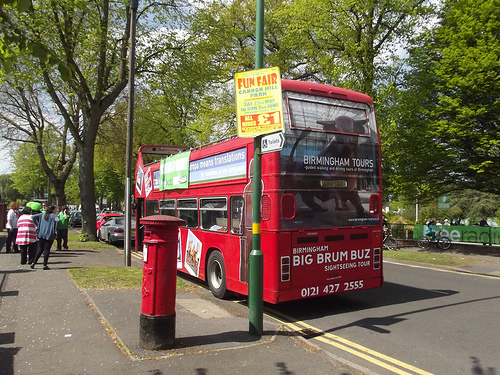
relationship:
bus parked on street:
[134, 79, 385, 304] [129, 240, 499, 375]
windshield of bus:
[282, 190, 381, 227] [134, 79, 385, 304]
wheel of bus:
[201, 250, 230, 304] [134, 79, 385, 304]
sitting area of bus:
[135, 129, 265, 168] [134, 79, 385, 304]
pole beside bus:
[247, 0, 269, 338] [134, 79, 385, 304]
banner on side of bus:
[156, 151, 192, 193] [134, 79, 385, 304]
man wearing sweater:
[30, 202, 59, 270] [31, 211, 60, 240]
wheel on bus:
[201, 250, 230, 304] [134, 79, 385, 304]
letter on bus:
[294, 255, 302, 267] [134, 79, 385, 304]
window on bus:
[198, 197, 230, 233] [134, 79, 385, 304]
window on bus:
[230, 194, 245, 235] [134, 79, 385, 304]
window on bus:
[175, 197, 200, 230] [134, 79, 385, 304]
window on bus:
[159, 197, 177, 220] [134, 79, 385, 304]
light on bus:
[279, 255, 291, 284] [134, 79, 385, 304]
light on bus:
[372, 246, 383, 271] [134, 79, 385, 304]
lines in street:
[235, 298, 431, 375] [129, 240, 499, 375]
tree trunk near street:
[78, 145, 103, 241] [129, 240, 499, 375]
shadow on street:
[238, 280, 459, 327] [129, 240, 499, 375]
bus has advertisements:
[134, 79, 385, 304] [276, 88, 382, 230]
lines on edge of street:
[235, 298, 431, 375] [129, 240, 499, 375]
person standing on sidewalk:
[15, 208, 41, 267] [1, 247, 354, 373]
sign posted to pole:
[231, 67, 286, 138] [247, 0, 269, 338]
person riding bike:
[425, 220, 437, 244] [413, 230, 452, 252]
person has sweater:
[15, 208, 41, 267] [15, 214, 37, 245]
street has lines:
[129, 240, 499, 375] [235, 298, 431, 375]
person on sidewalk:
[15, 208, 41, 267] [1, 247, 354, 373]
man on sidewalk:
[30, 202, 59, 270] [1, 247, 354, 373]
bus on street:
[134, 79, 385, 304] [129, 240, 499, 375]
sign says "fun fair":
[231, 67, 296, 134] [225, 73, 277, 86]